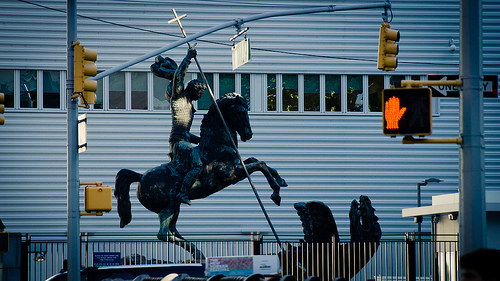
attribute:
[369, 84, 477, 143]
walk light — yellow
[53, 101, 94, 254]
pole — tall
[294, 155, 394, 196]
wall — blue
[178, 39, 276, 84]
sign — silver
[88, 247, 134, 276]
metal sign — blue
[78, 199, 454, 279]
fence — metal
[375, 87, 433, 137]
sign — red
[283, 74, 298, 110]
window — large, clear, building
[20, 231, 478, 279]
poles — metal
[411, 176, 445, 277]
light pole — small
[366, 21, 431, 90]
light — stop, hanging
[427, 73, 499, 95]
street sign — white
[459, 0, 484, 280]
pole — metal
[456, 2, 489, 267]
pole — metallic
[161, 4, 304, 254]
pole — long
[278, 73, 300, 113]
window — some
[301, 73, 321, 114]
window — some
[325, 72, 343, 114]
window — some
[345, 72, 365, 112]
window — some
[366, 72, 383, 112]
window — some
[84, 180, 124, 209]
walk light — yellow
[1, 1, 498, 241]
wall — gray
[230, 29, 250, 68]
sign — road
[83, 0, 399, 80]
pole — gray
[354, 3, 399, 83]
light — stop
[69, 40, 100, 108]
stop light — yellow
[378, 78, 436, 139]
sign — do not walk